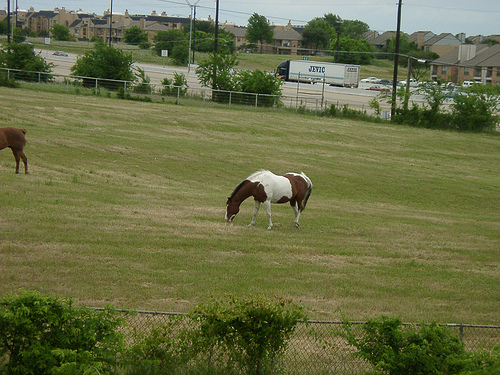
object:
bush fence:
[0, 284, 178, 375]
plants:
[67, 36, 141, 91]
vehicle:
[397, 77, 421, 87]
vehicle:
[366, 84, 391, 93]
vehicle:
[360, 76, 383, 84]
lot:
[367, 67, 500, 136]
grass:
[0, 82, 500, 373]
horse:
[223, 167, 313, 231]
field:
[0, 84, 499, 351]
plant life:
[189, 49, 287, 110]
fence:
[0, 63, 393, 122]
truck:
[273, 59, 362, 89]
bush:
[184, 294, 312, 374]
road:
[0, 49, 500, 133]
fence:
[0, 296, 500, 375]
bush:
[328, 303, 500, 375]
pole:
[389, 0, 403, 123]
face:
[226, 198, 239, 222]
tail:
[299, 182, 313, 214]